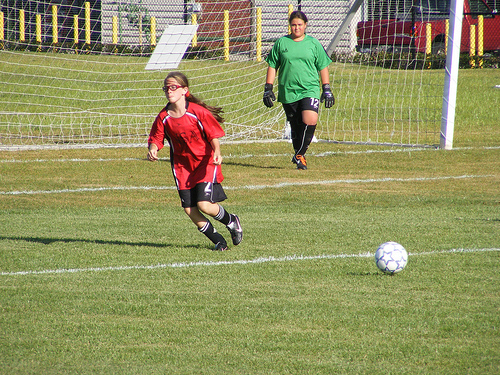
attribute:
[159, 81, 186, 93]
girl — running, standing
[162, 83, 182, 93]
eye glass — red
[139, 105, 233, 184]
shirt — red, green, short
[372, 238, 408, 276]
ball — white, round, black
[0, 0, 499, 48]
grass — green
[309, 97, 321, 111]
number — 12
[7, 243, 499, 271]
line — white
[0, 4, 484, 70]
pole — yellow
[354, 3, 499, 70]
truck — red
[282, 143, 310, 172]
shoe — orange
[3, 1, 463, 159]
goal net — for  Goal, soccer, white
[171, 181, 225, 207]
shorts — black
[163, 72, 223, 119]
hair — long